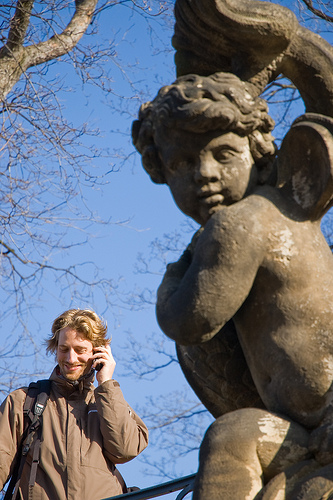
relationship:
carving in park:
[130, 0, 332, 499] [2, 4, 322, 490]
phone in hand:
[89, 347, 104, 369] [91, 341, 117, 388]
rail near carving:
[100, 470, 197, 499] [130, 0, 332, 499]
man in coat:
[4, 301, 147, 495] [0, 365, 146, 499]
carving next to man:
[129, 0, 332, 499] [4, 301, 147, 495]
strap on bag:
[23, 377, 52, 498] [1, 467, 23, 499]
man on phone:
[0, 306, 147, 500] [92, 341, 109, 373]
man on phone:
[0, 306, 147, 500] [93, 338, 104, 368]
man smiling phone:
[0, 306, 147, 500] [93, 338, 104, 368]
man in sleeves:
[0, 306, 147, 500] [84, 380, 145, 462]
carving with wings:
[130, 0, 332, 499] [172, 0, 332, 222]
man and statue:
[0, 306, 147, 500] [114, 61, 296, 247]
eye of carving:
[214, 152, 237, 162] [130, 0, 332, 499]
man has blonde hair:
[0, 306, 147, 500] [99, 68, 252, 140]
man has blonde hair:
[0, 306, 147, 500] [42, 306, 112, 363]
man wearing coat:
[4, 301, 147, 495] [0, 365, 146, 499]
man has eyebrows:
[4, 301, 147, 495] [57, 341, 87, 352]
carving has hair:
[130, 0, 332, 499] [126, 72, 282, 163]